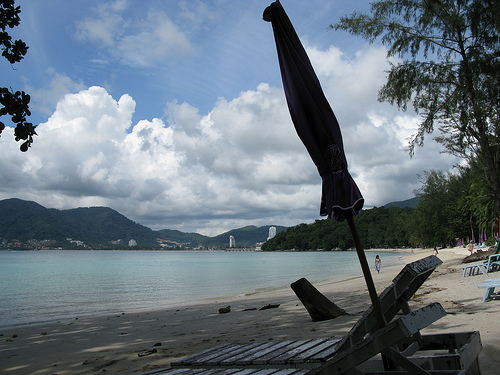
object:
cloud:
[3, 87, 194, 205]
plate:
[64, 194, 196, 242]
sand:
[378, 250, 498, 374]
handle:
[408, 254, 445, 278]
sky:
[0, 0, 499, 237]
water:
[5, 247, 79, 268]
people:
[375, 254, 382, 273]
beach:
[5, 317, 213, 372]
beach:
[351, 231, 489, 336]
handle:
[345, 211, 398, 371]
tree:
[334, 1, 498, 231]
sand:
[207, 303, 337, 353]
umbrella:
[262, 2, 401, 375]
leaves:
[13, 119, 35, 151]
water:
[0, 305, 69, 329]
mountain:
[0, 197, 161, 258]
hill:
[152, 229, 215, 251]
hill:
[214, 225, 285, 247]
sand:
[2, 314, 158, 371]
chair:
[132, 301, 445, 374]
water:
[244, 255, 345, 281]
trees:
[413, 170, 458, 250]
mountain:
[259, 197, 428, 250]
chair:
[173, 253, 445, 368]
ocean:
[0, 248, 405, 329]